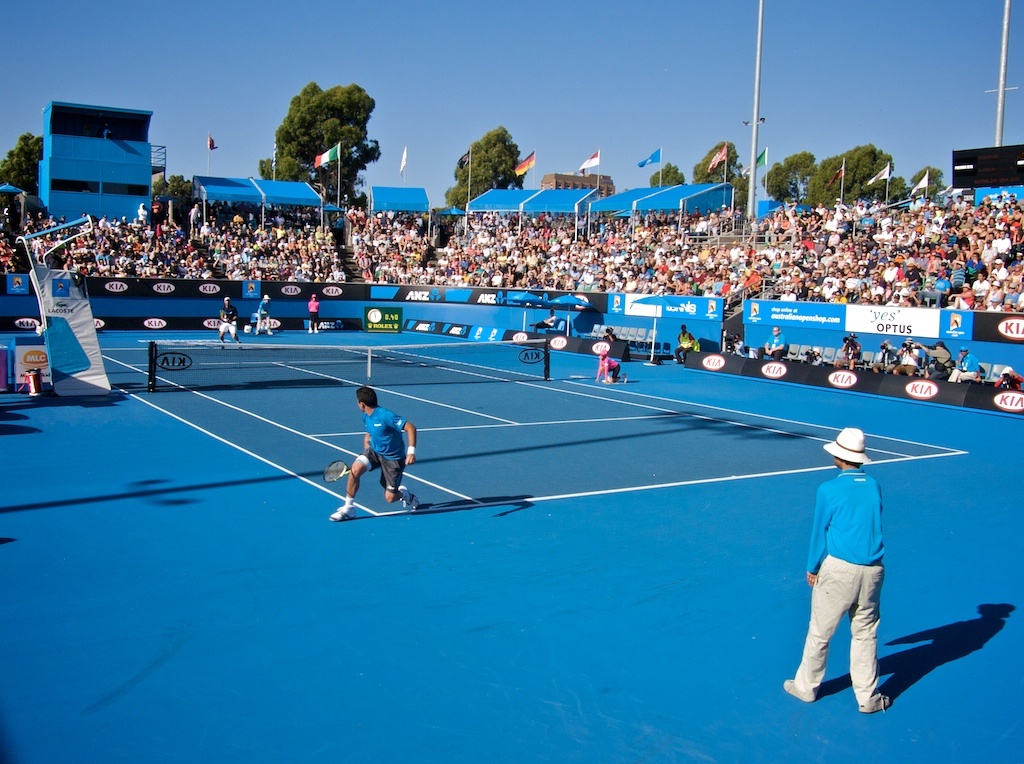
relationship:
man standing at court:
[774, 416, 893, 717] [52, 280, 994, 732]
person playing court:
[322, 381, 420, 533] [0, 329, 1024, 764]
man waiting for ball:
[209, 292, 244, 350] [233, 293, 279, 330]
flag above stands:
[640, 143, 664, 170] [22, 182, 977, 427]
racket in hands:
[324, 451, 354, 481] [348, 458, 359, 478]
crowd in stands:
[2, 183, 1017, 308] [6, 188, 989, 387]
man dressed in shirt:
[783, 427, 890, 714] [807, 469, 885, 575]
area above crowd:
[32, 94, 165, 235] [47, 204, 983, 298]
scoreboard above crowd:
[941, 143, 1021, 197] [32, 184, 992, 381]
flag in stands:
[511, 148, 537, 181] [185, 115, 991, 250]